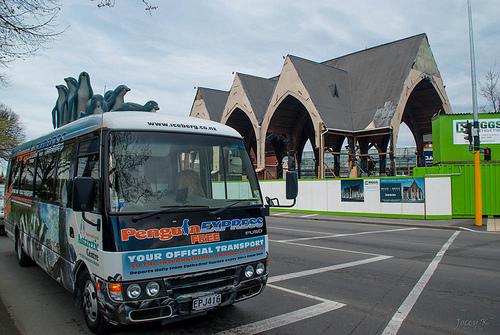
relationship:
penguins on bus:
[50, 71, 163, 127] [4, 108, 270, 329]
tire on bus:
[77, 270, 110, 334] [4, 108, 270, 329]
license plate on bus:
[191, 292, 225, 311] [4, 108, 270, 329]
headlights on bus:
[126, 280, 162, 299] [4, 108, 270, 329]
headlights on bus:
[242, 260, 267, 279] [4, 108, 270, 329]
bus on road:
[4, 108, 270, 329] [3, 217, 497, 333]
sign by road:
[337, 174, 428, 205] [3, 217, 497, 333]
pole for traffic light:
[466, 1, 482, 229] [460, 119, 494, 164]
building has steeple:
[188, 32, 450, 173] [392, 31, 457, 122]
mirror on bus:
[283, 148, 299, 205] [4, 108, 270, 329]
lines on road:
[210, 223, 467, 334] [3, 217, 497, 333]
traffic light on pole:
[460, 119, 494, 164] [466, 1, 482, 229]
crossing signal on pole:
[484, 146, 493, 165] [466, 1, 482, 229]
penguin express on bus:
[118, 215, 265, 240] [4, 108, 270, 329]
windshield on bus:
[106, 132, 268, 211] [4, 108, 270, 329]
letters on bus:
[118, 227, 138, 242] [4, 108, 270, 329]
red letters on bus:
[125, 242, 266, 269] [4, 108, 270, 329]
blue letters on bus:
[199, 214, 266, 232] [4, 108, 270, 329]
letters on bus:
[77, 234, 98, 251] [4, 108, 270, 329]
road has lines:
[3, 217, 497, 333] [374, 226, 462, 334]